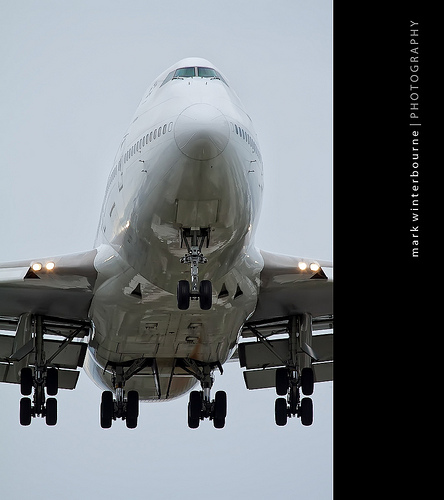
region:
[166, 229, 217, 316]
landing gear down on the front of the plane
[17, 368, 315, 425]
landing gear down on the back of the plane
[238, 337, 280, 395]
flaps down on the wings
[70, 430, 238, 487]
white blue sky behind the plane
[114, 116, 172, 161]
row of windows at the front of the plane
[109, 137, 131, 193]
door at the front of the plane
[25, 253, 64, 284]
lights on the wing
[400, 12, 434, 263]
photo tag on the picture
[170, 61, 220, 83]
cockpit windows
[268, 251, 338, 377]
wing of the plane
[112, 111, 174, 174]
passenger windows on airplane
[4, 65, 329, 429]
photograph of white airplane in the air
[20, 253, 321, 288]
two lights on each airplane wing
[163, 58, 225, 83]
windows on airplane for pilots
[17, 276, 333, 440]
black wheels on airplane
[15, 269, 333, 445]
wheels in the down position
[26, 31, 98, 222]
light sky with no clouds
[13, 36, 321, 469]
photograph taken from underneath the plane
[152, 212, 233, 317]
only two wheels in the front of the plane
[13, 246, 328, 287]
lights lit up on wings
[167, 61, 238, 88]
Large windshield on front of plane.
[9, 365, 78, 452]
Black wheels on bottom of plane.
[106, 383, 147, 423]
Black wheels on bottom of plane.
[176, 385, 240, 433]
Black wheels on bottom of plane.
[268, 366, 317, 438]
Black wheels on bottom of plane.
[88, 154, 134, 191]
White door on side of plane.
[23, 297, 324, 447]
Landing gear is down on plane.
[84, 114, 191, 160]
Windows line side of lane.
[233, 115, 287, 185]
Windows line side of plane.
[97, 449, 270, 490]
Sky is grayish blue.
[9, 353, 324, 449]
lowered landing gear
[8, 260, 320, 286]
lights on wings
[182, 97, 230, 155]
nose of plane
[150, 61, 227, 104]
pilot's place in the cockpit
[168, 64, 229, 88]
windshield wipers on the plane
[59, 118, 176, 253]
windows for passengers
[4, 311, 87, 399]
panels are part of the wing assembly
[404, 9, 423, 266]
name of photographer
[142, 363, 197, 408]
doors to the storage area for the landing gear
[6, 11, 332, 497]
a grey sky over plane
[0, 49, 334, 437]
plane in the air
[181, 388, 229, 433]
wheels on the plane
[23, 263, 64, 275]
lights on the plane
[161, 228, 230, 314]
landing gear on the plane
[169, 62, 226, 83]
windows on the plane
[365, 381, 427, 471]
black on the photo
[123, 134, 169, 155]
windows on the plane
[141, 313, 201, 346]
underbelly of the plane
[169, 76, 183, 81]
wiper on the window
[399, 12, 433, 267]
words on the photo